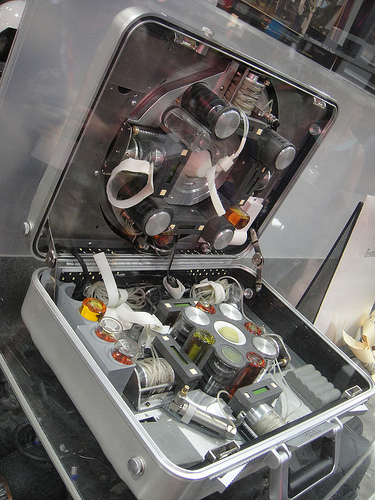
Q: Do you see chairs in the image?
A: No, there are no chairs.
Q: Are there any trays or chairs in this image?
A: No, there are no chairs or trays.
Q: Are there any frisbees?
A: No, there are no frisbees.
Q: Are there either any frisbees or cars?
A: No, there are no frisbees or cars.